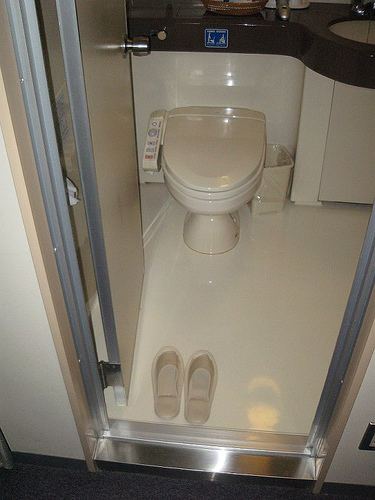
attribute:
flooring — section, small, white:
[279, 370, 318, 396]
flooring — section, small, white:
[285, 210, 332, 234]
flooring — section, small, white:
[275, 278, 317, 287]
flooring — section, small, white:
[199, 279, 236, 297]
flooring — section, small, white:
[201, 313, 276, 348]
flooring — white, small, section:
[238, 228, 326, 379]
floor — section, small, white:
[91, 182, 372, 434]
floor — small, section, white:
[273, 357, 290, 380]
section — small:
[264, 306, 329, 360]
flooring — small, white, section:
[90, 182, 372, 435]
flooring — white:
[287, 203, 359, 253]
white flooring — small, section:
[95, 182, 374, 436]